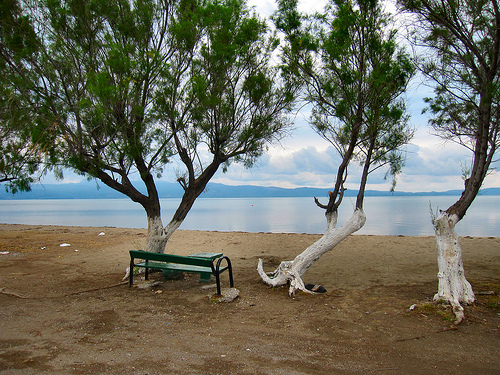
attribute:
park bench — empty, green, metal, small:
[117, 247, 238, 295]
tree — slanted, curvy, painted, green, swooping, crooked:
[395, 0, 499, 322]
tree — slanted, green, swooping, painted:
[258, 0, 419, 298]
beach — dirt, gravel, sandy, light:
[1, 222, 499, 374]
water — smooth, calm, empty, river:
[1, 198, 497, 242]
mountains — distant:
[2, 178, 499, 195]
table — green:
[188, 252, 223, 280]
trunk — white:
[426, 92, 496, 328]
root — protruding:
[257, 256, 286, 288]